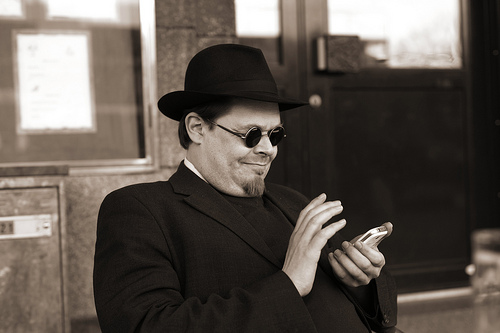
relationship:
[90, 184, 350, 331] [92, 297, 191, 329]
arm bent at elbow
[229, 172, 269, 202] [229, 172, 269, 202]
chin on chin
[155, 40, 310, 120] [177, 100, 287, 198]
black hat on head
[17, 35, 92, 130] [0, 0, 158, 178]
sign on window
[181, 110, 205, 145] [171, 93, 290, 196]
ear on head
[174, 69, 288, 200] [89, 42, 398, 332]
head of man